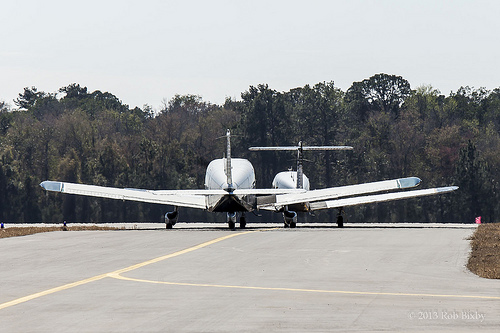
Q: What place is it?
A: It is a pavement.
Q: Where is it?
A: This is at the pavement.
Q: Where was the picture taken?
A: It was taken at the pavement.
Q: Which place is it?
A: It is a pavement.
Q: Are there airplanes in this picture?
A: Yes, there is an airplane.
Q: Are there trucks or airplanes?
A: Yes, there is an airplane.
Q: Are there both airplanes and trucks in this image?
A: No, there is an airplane but no trucks.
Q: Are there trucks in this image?
A: No, there are no trucks.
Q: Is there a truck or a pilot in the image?
A: No, there are no trucks or pilots.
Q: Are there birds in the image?
A: No, there are no birds.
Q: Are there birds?
A: No, there are no birds.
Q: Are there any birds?
A: No, there are no birds.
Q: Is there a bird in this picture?
A: No, there are no birds.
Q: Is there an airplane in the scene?
A: Yes, there is an airplane.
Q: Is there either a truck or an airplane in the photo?
A: Yes, there is an airplane.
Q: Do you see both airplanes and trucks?
A: No, there is an airplane but no trucks.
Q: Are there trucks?
A: No, there are no trucks.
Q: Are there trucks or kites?
A: No, there are no trucks or kites.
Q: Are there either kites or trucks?
A: No, there are no trucks or kites.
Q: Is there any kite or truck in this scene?
A: No, there are no trucks or kites.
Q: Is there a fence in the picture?
A: No, there are no fences.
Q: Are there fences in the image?
A: No, there are no fences.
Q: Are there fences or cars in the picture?
A: No, there are no fences or cars.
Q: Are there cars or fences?
A: No, there are no fences or cars.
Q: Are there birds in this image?
A: No, there are no birds.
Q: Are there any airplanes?
A: Yes, there is an airplane.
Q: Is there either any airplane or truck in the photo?
A: Yes, there is an airplane.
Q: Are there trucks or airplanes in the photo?
A: Yes, there is an airplane.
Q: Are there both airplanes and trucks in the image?
A: No, there is an airplane but no trucks.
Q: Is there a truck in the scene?
A: No, there are no trucks.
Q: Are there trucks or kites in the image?
A: No, there are no trucks or kites.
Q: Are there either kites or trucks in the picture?
A: No, there are no trucks or kites.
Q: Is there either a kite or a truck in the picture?
A: No, there are no trucks or kites.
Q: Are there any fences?
A: No, there are no fences.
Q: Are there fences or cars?
A: No, there are no fences or cars.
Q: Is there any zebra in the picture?
A: No, there are no zebras.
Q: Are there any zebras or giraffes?
A: No, there are no zebras or giraffes.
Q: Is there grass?
A: Yes, there is grass.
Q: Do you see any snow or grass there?
A: Yes, there is grass.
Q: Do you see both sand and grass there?
A: No, there is grass but no sand.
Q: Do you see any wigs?
A: No, there are no wigs.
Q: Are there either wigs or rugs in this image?
A: No, there are no wigs or rugs.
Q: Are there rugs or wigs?
A: No, there are no wigs or rugs.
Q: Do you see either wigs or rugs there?
A: No, there are no wigs or rugs.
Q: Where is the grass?
A: The grass is on the ground.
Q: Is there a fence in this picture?
A: No, there are no fences.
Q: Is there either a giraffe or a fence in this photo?
A: No, there are no fences or giraffes.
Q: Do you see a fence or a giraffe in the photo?
A: No, there are no fences or giraffes.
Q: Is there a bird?
A: No, there are no birds.